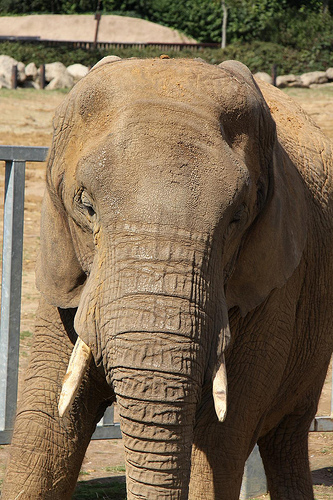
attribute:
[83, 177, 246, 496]
elephant trunk — wrinkled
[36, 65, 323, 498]
elephant — wrinkle, brown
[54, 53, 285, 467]
elephant — grey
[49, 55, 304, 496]
elephant — brown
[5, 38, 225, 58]
railing — redwood colored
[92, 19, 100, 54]
pole — utility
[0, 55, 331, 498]
elephant — brown, grey, gray